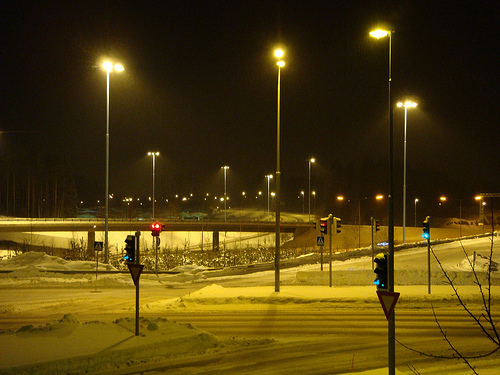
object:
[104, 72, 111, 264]
pole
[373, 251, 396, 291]
signal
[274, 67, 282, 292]
light pole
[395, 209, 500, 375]
twig branches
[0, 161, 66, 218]
tree trunks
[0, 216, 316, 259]
overpass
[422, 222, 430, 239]
green light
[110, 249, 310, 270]
plants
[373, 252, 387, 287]
greenlight signal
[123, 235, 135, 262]
greenlight signal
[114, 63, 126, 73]
lamp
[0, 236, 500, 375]
road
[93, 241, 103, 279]
sign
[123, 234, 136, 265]
signal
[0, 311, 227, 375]
snow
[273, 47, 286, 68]
lights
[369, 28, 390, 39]
lights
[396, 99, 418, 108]
lights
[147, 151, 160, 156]
lights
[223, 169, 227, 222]
pole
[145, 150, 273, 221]
streetlights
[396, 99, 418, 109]
signal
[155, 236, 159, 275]
pole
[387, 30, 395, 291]
pole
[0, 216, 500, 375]
street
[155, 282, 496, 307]
snow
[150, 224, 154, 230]
light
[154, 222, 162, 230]
light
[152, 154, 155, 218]
light pole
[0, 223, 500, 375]
ground